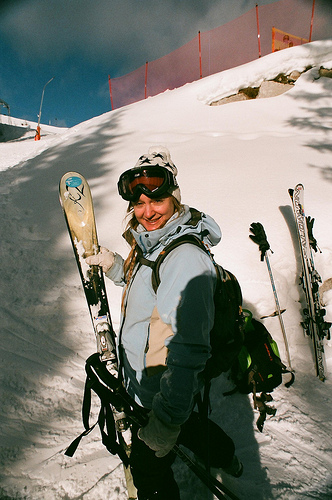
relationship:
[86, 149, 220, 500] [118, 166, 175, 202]
woman wearing goggles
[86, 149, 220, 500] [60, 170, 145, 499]
woman holding skis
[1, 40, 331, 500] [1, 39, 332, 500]
ground has snow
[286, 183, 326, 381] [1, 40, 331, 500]
skis on ground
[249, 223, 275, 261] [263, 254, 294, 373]
gloves on pole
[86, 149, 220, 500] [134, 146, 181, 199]
woman has hat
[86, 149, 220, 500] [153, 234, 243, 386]
woman has backpack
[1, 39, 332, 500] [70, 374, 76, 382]
snow has spot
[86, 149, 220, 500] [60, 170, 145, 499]
woman has skis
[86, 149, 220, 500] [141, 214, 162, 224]
woman has grin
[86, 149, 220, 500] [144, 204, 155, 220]
woman has nose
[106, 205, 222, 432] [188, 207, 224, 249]
top has hood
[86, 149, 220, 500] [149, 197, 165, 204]
woman has eye